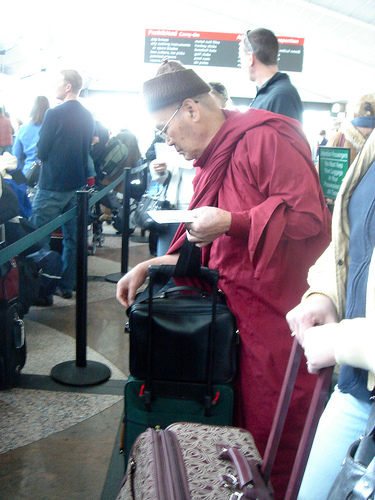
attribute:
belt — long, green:
[6, 142, 346, 375]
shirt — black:
[35, 104, 105, 196]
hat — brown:
[141, 61, 209, 112]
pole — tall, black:
[69, 180, 114, 291]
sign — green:
[314, 140, 355, 208]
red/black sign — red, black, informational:
[139, 23, 308, 74]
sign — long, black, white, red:
[130, 18, 333, 87]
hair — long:
[28, 95, 49, 128]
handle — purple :
[213, 441, 257, 497]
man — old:
[112, 65, 372, 367]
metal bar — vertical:
[72, 191, 92, 367]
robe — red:
[152, 107, 325, 435]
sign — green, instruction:
[310, 118, 352, 227]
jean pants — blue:
[28, 189, 77, 296]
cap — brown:
[141, 57, 212, 114]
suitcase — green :
[118, 372, 237, 460]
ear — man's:
[175, 95, 203, 122]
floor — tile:
[12, 385, 123, 493]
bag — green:
[117, 372, 233, 471]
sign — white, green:
[318, 147, 353, 186]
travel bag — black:
[102, 255, 266, 336]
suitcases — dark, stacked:
[117, 263, 241, 474]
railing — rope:
[9, 155, 155, 258]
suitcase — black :
[123, 263, 240, 474]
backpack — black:
[19, 230, 71, 306]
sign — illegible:
[142, 25, 305, 74]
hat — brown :
[140, 57, 203, 115]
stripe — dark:
[43, 364, 118, 404]